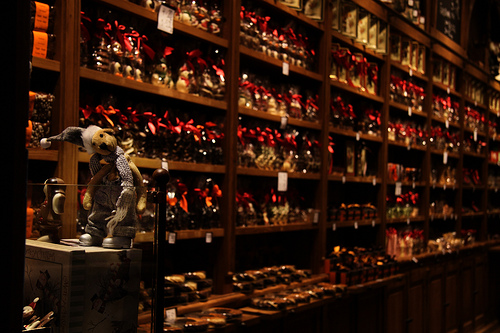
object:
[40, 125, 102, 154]
hat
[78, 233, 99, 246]
shoes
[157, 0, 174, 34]
paper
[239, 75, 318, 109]
shelf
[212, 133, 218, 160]
items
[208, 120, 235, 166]
items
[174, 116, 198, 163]
items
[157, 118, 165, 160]
items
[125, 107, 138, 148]
items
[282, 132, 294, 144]
redribbon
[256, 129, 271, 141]
redribbon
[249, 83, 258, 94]
redribbon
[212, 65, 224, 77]
redribbon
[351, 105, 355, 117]
redribbon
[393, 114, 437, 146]
toys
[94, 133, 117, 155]
dog face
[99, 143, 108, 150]
black nose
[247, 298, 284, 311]
toy car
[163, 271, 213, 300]
toy car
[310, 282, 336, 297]
toy car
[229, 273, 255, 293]
toy car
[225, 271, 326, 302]
shelf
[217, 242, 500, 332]
cabinets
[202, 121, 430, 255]
goods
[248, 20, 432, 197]
wooden racks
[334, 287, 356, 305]
knob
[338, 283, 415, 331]
cabinet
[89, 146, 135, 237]
scarf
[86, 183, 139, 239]
pants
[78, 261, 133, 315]
design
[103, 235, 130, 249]
shoes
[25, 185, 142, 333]
glass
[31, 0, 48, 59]
labels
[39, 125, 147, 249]
animal